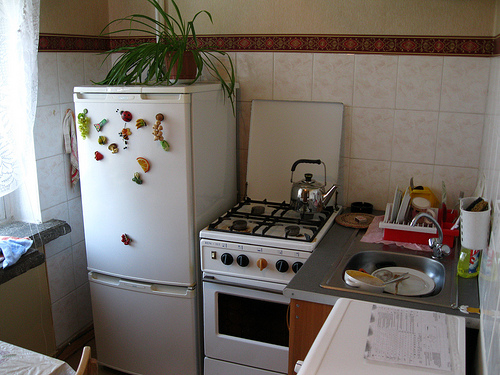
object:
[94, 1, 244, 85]
plant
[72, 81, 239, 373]
refrigerator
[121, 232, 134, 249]
magnet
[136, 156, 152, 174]
magnet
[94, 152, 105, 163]
magnet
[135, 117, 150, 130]
magnet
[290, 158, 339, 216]
teakettle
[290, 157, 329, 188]
handle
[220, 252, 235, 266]
knob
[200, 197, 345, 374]
stove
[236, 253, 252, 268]
knob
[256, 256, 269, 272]
knob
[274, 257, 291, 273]
knob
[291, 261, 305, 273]
knob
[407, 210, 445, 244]
faucet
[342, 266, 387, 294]
dishes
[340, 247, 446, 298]
sink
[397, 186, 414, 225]
dish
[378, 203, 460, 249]
holder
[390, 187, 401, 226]
dish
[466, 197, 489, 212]
sponge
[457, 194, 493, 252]
holder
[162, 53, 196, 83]
pot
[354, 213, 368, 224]
matches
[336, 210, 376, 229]
mat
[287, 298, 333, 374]
cabinet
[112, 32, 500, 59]
border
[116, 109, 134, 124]
magnet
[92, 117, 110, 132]
magnet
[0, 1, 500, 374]
kitchen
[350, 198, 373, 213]
ashtray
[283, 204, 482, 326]
counter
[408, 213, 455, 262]
tap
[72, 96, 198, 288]
door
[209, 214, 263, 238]
burner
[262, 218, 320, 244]
burner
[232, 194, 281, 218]
burner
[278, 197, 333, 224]
burner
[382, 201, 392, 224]
dishes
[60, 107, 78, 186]
towel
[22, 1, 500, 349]
wall